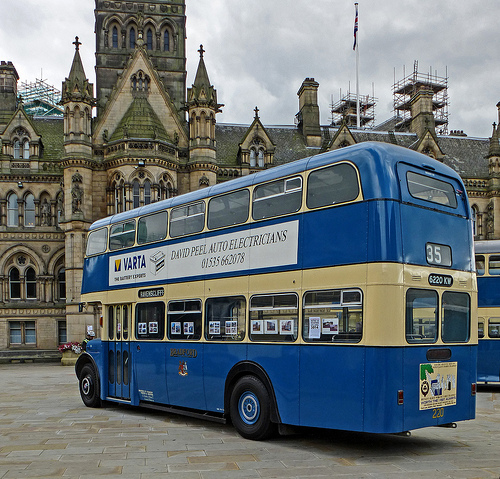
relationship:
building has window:
[2, 2, 484, 364] [2, 188, 26, 230]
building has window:
[2, 2, 484, 364] [8, 184, 22, 233]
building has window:
[2, 2, 484, 364] [1, 256, 24, 308]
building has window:
[2, 2, 484, 364] [7, 317, 26, 353]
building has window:
[2, 2, 484, 364] [11, 130, 32, 163]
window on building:
[7, 280, 22, 301] [2, 2, 484, 364]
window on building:
[7, 319, 26, 347] [2, 2, 484, 364]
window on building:
[17, 131, 36, 160] [2, 2, 484, 364]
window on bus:
[303, 161, 360, 212] [58, 137, 480, 441]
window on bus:
[403, 287, 442, 344] [58, 137, 480, 441]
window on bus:
[406, 170, 457, 205] [58, 137, 480, 441]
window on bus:
[203, 183, 247, 231] [58, 137, 480, 441]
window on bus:
[308, 161, 360, 203] [58, 137, 480, 441]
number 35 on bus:
[425, 242, 441, 267] [74, 141, 484, 456]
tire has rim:
[219, 371, 279, 445] [235, 393, 262, 423]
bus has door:
[74, 141, 484, 456] [102, 298, 138, 401]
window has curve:
[404, 168, 459, 210] [398, 160, 423, 202]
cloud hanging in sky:
[0, 0, 499, 142] [1, 2, 484, 134]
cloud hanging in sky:
[322, 71, 401, 125] [1, 2, 484, 134]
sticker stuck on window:
[168, 320, 182, 336] [166, 308, 203, 339]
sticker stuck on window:
[182, 320, 195, 334] [166, 308, 203, 339]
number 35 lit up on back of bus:
[425, 242, 441, 267] [74, 141, 484, 456]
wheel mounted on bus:
[225, 372, 277, 439] [74, 141, 484, 456]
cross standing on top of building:
[252, 104, 261, 117] [2, 2, 484, 364]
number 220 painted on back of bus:
[430, 405, 446, 419] [74, 141, 484, 456]